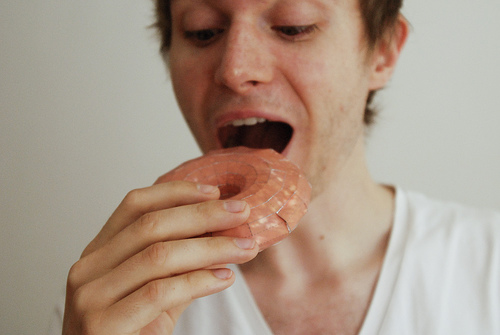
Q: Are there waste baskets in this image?
A: No, there are no waste baskets.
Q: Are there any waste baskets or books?
A: No, there are no waste baskets or books.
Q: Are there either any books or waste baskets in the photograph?
A: No, there are no waste baskets or books.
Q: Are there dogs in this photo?
A: No, there are no dogs.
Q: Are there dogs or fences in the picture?
A: No, there are no dogs or fences.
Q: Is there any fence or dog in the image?
A: No, there are no dogs or fences.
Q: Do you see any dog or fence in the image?
A: No, there are no dogs or fences.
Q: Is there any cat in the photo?
A: No, there are no cats.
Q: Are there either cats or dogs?
A: No, there are no cats or dogs.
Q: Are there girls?
A: No, there are no girls.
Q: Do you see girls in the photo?
A: No, there are no girls.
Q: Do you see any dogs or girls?
A: No, there are no girls or dogs.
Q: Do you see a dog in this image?
A: No, there are no dogs.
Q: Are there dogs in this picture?
A: No, there are no dogs.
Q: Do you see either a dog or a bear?
A: No, there are no dogs or bears.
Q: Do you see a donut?
A: Yes, there is a donut.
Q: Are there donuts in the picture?
A: Yes, there is a donut.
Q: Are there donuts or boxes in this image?
A: Yes, there is a donut.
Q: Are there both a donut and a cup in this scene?
A: No, there is a donut but no cups.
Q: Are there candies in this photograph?
A: No, there are no candies.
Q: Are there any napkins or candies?
A: No, there are no candies or napkins.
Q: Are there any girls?
A: No, there are no girls.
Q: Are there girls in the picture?
A: No, there are no girls.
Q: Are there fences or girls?
A: No, there are no girls or fences.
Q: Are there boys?
A: No, there are no boys.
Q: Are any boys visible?
A: No, there are no boys.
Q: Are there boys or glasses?
A: No, there are no boys or glasses.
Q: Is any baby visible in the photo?
A: No, there are no babies.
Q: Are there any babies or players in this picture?
A: No, there are no babies or players.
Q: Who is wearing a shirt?
A: The man is wearing a shirt.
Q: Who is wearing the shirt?
A: The man is wearing a shirt.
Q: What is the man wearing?
A: The man is wearing a shirt.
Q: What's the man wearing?
A: The man is wearing a shirt.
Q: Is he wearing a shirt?
A: Yes, the man is wearing a shirt.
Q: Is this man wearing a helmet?
A: No, the man is wearing a shirt.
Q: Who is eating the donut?
A: The man is eating the donut.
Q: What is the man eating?
A: The man is eating a donut.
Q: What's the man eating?
A: The man is eating a donut.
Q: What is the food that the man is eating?
A: The food is a donut.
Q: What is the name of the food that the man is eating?
A: The food is a donut.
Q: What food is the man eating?
A: The man is eating a doughnut.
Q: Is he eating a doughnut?
A: Yes, the man is eating a doughnut.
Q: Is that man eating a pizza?
A: No, the man is eating a doughnut.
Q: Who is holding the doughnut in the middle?
A: The man is holding the donut.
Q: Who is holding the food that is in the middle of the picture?
A: The man is holding the donut.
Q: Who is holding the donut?
A: The man is holding the donut.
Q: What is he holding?
A: The man is holding the donut.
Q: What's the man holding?
A: The man is holding the donut.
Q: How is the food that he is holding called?
A: The food is a donut.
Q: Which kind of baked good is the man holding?
A: The man is holding the doughnut.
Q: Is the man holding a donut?
A: Yes, the man is holding a donut.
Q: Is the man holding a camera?
A: No, the man is holding a donut.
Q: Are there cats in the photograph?
A: No, there are no cats.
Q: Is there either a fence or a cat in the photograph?
A: No, there are no cats or fences.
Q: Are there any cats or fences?
A: No, there are no cats or fences.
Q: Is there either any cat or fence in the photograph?
A: No, there are no cats or fences.